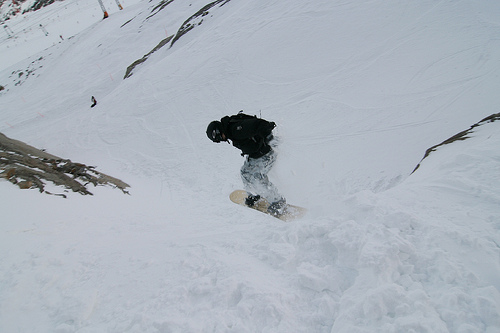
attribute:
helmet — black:
[206, 117, 231, 142]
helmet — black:
[205, 119, 222, 144]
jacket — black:
[219, 107, 277, 160]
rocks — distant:
[121, 4, 219, 81]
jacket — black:
[229, 107, 300, 174]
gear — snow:
[239, 120, 271, 159]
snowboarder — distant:
[84, 90, 130, 130]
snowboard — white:
[228, 189, 305, 224]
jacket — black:
[225, 108, 277, 167]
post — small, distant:
[114, 1, 124, 11]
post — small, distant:
[95, 1, 107, 20]